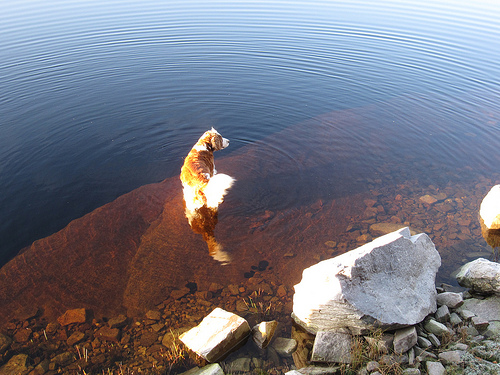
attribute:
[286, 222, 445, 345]
stone — big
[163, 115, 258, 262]
dog — white, brown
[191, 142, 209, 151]
neck — white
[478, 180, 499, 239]
rock — large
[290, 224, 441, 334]
rock — large, square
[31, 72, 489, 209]
water — clear, clean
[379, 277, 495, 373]
stones — small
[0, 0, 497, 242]
water — calm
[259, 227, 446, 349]
rock — white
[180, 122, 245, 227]
dog — swimming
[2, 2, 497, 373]
water — calm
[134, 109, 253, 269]
dog — brown, white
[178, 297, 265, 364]
rock — large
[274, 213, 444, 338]
stone — big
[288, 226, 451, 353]
rock — big